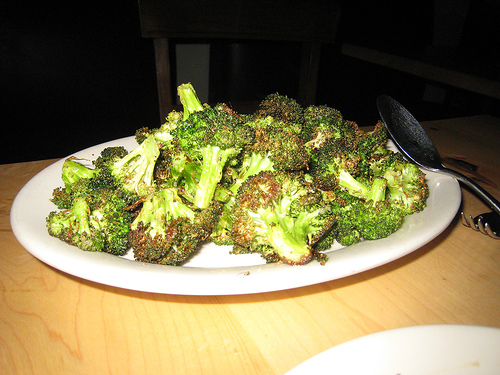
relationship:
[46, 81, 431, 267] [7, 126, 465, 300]
broccoli on plate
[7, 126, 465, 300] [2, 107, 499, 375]
plate on table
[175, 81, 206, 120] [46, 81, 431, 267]
stem of broccoli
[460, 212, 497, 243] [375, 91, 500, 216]
tines of utensils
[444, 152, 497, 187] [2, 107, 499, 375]
knot in table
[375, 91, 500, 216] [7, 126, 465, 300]
utensils on plate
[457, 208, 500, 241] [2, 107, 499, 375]
utensils on table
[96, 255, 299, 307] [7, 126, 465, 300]
edge of plate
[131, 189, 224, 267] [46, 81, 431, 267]
piece of broccoli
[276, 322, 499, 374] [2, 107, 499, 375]
plate on table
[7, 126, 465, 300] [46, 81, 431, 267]
plate of broccoli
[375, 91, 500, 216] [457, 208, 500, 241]
utensils and utensils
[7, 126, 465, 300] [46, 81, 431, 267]
plate filled with broccoli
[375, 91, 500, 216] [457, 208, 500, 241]
utensils beside utensils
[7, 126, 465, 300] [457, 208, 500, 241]
plate beside utensils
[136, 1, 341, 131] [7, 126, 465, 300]
chair behind plate